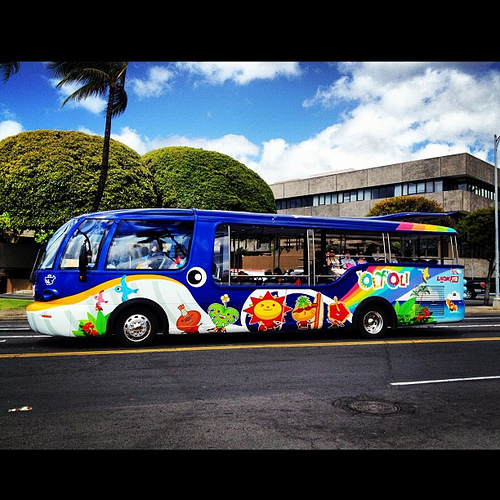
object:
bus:
[24, 207, 468, 347]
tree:
[45, 62, 131, 211]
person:
[328, 250, 341, 281]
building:
[268, 154, 499, 305]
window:
[395, 183, 403, 197]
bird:
[115, 272, 139, 302]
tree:
[139, 145, 279, 213]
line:
[0, 336, 500, 360]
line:
[390, 377, 499, 387]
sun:
[242, 291, 293, 332]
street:
[2, 320, 499, 498]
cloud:
[175, 63, 309, 88]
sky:
[1, 62, 499, 183]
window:
[211, 222, 308, 290]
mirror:
[79, 243, 89, 282]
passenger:
[356, 251, 368, 266]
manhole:
[348, 399, 398, 414]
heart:
[207, 302, 240, 332]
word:
[355, 269, 410, 291]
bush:
[0, 130, 157, 228]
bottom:
[29, 316, 469, 337]